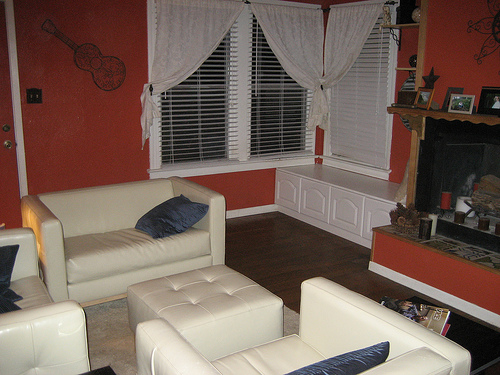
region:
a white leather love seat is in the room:
[22, 172, 231, 297]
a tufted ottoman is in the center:
[128, 260, 285, 352]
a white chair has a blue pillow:
[134, 278, 469, 373]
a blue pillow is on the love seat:
[64, 182, 219, 288]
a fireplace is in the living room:
[368, 100, 498, 317]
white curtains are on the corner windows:
[141, 0, 396, 182]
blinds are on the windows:
[152, 1, 394, 176]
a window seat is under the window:
[272, 160, 414, 250]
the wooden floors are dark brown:
[223, 208, 490, 373]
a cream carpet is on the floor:
[6, 284, 306, 373]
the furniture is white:
[11, 129, 346, 368]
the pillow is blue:
[120, 166, 253, 268]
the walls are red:
[51, 54, 181, 184]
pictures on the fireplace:
[319, 51, 464, 220]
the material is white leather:
[70, 148, 257, 324]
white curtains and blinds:
[151, 16, 348, 168]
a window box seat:
[247, 103, 487, 295]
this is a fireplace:
[331, 6, 493, 208]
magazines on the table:
[353, 274, 496, 353]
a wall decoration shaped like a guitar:
[23, 8, 185, 134]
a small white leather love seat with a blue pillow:
[24, 184, 240, 289]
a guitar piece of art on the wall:
[28, 15, 134, 99]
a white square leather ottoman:
[128, 272, 283, 347]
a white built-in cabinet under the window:
[281, 171, 399, 247]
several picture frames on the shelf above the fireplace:
[398, 86, 499, 118]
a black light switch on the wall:
[23, 84, 43, 106]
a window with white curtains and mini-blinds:
[146, 0, 325, 174]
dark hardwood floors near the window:
[233, 223, 346, 290]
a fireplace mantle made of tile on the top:
[371, 227, 498, 307]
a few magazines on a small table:
[381, 293, 458, 338]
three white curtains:
[136, 0, 384, 156]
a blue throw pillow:
[132, 185, 209, 240]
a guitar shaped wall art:
[35, 11, 130, 93]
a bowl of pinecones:
[385, 195, 430, 230]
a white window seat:
[265, 157, 405, 252]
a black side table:
[370, 290, 495, 371]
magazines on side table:
[371, 287, 496, 368]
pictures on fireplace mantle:
[385, 76, 495, 121]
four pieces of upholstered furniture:
[0, 169, 472, 374]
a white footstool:
[125, 261, 282, 361]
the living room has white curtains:
[141, 3, 323, 177]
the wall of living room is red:
[25, 9, 145, 187]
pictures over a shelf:
[387, 76, 498, 110]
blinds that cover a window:
[163, 11, 310, 161]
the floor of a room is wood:
[239, 214, 329, 269]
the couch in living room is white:
[17, 173, 228, 276]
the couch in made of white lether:
[16, 173, 235, 273]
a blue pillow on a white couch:
[133, 190, 208, 240]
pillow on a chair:
[273, 335, 394, 371]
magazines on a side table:
[379, 279, 459, 337]